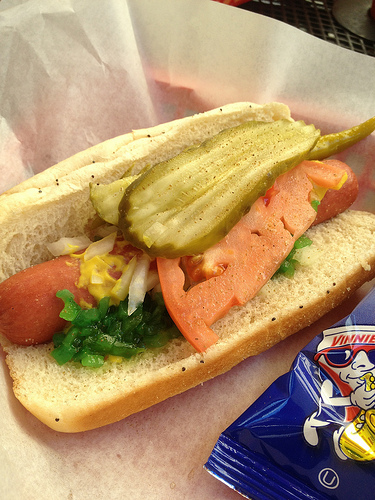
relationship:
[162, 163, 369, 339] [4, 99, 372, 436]
tomato on bun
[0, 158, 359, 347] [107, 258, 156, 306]
dog with onions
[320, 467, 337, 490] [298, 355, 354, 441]
letter u on bag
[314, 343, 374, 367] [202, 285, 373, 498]
sunglasses on bag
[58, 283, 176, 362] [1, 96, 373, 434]
relish on hot dog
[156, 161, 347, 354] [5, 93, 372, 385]
tomato on bun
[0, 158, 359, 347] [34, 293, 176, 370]
dog with relish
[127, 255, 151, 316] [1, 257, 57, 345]
onion on hotdog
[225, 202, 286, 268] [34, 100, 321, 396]
pepper on bread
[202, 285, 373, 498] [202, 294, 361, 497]
bag of potato chips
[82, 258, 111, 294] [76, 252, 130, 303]
mustard on dog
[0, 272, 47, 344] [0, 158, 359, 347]
end of dog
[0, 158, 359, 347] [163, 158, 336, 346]
dog with tomato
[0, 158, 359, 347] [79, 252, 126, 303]
dog with mustard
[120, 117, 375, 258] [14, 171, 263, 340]
pickle on a hotdog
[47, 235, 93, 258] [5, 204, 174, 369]
onion on a hot dog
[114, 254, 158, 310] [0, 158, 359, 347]
onion on a dog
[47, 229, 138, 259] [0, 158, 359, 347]
onion on a dog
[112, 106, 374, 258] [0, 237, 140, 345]
pickle on a hot dog